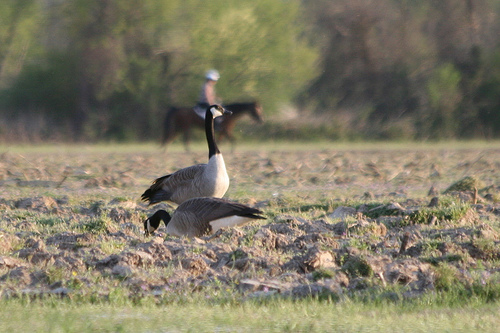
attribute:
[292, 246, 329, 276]
rock — grey 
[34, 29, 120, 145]
tree — green 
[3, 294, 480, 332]
grass — green 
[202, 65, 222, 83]
helmet — white 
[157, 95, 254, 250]
goose — canadian, eating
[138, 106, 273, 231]
goose — white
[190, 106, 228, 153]
neck — black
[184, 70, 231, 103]
man — riding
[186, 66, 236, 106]
man — riding